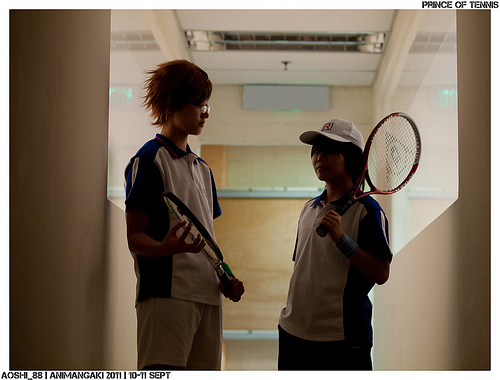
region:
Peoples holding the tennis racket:
[136, 54, 437, 364]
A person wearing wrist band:
[334, 229, 359, 259]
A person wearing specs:
[193, 100, 214, 115]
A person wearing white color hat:
[291, 100, 356, 150]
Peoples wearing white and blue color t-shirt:
[128, 169, 400, 278]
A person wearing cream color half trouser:
[138, 309, 220, 350]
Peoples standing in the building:
[131, 52, 439, 357]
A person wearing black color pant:
[281, 349, 347, 371]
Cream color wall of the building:
[439, 237, 476, 320]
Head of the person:
[142, 55, 222, 136]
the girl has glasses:
[134, 70, 234, 377]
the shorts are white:
[139, 298, 232, 355]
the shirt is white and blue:
[126, 151, 235, 301]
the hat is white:
[299, 109, 374, 147]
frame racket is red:
[365, 103, 385, 198]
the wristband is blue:
[333, 231, 358, 256]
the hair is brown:
[145, 53, 201, 115]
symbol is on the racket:
[374, 134, 411, 187]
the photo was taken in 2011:
[104, 372, 128, 379]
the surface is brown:
[232, 205, 287, 311]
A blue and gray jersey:
[128, 139, 228, 299]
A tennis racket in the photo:
[169, 190, 236, 290]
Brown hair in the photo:
[132, 54, 186, 99]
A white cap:
[293, 114, 362, 145]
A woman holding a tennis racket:
[312, 97, 436, 253]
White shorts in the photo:
[122, 298, 227, 363]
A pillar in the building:
[50, 138, 92, 280]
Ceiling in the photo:
[259, 23, 316, 100]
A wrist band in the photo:
[327, 233, 363, 260]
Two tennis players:
[145, 62, 392, 367]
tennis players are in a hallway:
[41, 18, 472, 357]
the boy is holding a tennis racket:
[117, 61, 248, 320]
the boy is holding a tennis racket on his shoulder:
[275, 99, 424, 245]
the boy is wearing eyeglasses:
[183, 90, 222, 132]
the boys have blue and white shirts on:
[117, 131, 397, 343]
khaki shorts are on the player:
[131, 290, 227, 378]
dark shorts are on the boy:
[271, 318, 374, 370]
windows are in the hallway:
[97, 13, 479, 280]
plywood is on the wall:
[190, 190, 332, 343]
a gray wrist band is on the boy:
[331, 229, 359, 261]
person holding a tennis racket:
[260, 99, 424, 373]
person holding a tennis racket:
[112, 56, 253, 371]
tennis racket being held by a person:
[160, 187, 250, 306]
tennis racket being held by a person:
[310, 106, 427, 242]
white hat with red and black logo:
[296, 113, 370, 157]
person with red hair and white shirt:
[110, 48, 238, 378]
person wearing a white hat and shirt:
[265, 94, 428, 375]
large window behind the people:
[375, 6, 460, 255]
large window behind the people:
[107, 8, 204, 215]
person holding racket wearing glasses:
[118, 57, 233, 377]